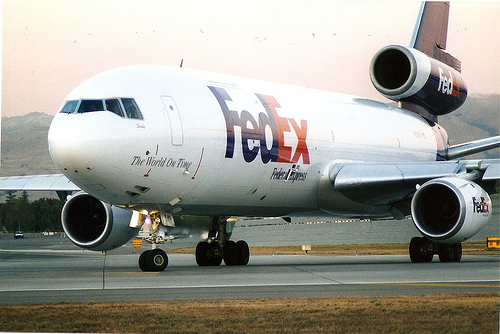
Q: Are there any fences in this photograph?
A: No, there are no fences.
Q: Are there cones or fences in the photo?
A: No, there are no fences or cones.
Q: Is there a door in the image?
A: Yes, there is a door.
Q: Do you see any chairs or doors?
A: Yes, there is a door.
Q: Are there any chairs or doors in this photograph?
A: Yes, there is a door.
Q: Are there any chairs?
A: No, there are no chairs.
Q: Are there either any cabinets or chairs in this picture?
A: No, there are no chairs or cabinets.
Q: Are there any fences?
A: No, there are no fences.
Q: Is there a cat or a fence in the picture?
A: No, there are no fences or cats.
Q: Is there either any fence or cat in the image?
A: No, there are no fences or cats.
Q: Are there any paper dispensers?
A: No, there are no paper dispensers.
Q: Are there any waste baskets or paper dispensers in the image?
A: No, there are no paper dispensers or waste baskets.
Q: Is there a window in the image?
A: Yes, there is a window.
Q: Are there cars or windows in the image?
A: Yes, there is a window.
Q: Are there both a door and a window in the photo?
A: Yes, there are both a window and a door.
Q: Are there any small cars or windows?
A: Yes, there is a small window.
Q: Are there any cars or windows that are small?
A: Yes, the window is small.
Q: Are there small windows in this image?
A: Yes, there is a small window.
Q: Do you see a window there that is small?
A: Yes, there is a small window.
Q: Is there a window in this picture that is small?
A: Yes, there is a window that is small.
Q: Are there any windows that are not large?
A: Yes, there is a small window.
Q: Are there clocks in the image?
A: No, there are no clocks.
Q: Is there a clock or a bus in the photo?
A: No, there are no clocks or buses.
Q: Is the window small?
A: Yes, the window is small.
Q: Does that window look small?
A: Yes, the window is small.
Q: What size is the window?
A: The window is small.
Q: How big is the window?
A: The window is small.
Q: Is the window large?
A: No, the window is small.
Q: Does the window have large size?
A: No, the window is small.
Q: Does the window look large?
A: No, the window is small.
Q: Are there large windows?
A: No, there is a window but it is small.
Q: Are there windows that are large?
A: No, there is a window but it is small.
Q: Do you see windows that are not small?
A: No, there is a window but it is small.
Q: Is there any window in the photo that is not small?
A: No, there is a window but it is small.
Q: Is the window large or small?
A: The window is small.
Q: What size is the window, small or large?
A: The window is small.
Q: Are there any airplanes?
A: Yes, there is an airplane.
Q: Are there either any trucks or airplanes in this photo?
A: Yes, there is an airplane.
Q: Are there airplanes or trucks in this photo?
A: Yes, there is an airplane.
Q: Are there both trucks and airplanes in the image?
A: No, there is an airplane but no trucks.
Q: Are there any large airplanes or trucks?
A: Yes, there is a large airplane.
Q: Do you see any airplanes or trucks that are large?
A: Yes, the airplane is large.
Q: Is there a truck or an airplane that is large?
A: Yes, the airplane is large.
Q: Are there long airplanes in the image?
A: Yes, there is a long airplane.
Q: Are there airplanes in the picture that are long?
A: Yes, there is an airplane that is long.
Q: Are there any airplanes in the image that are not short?
A: Yes, there is a long airplane.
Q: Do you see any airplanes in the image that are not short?
A: Yes, there is a long airplane.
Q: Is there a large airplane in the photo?
A: Yes, there is a large airplane.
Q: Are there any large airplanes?
A: Yes, there is a large airplane.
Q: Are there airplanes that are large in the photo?
A: Yes, there is a large airplane.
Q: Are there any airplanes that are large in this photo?
A: Yes, there is a large airplane.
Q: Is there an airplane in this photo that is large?
A: Yes, there is an airplane that is large.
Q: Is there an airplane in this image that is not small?
A: Yes, there is a large airplane.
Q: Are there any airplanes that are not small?
A: Yes, there is a large airplane.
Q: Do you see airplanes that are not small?
A: Yes, there is a large airplane.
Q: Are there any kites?
A: No, there are no kites.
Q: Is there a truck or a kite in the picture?
A: No, there are no kites or trucks.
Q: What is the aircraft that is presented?
A: The aircraft is an airplane.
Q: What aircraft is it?
A: The aircraft is an airplane.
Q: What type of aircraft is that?
A: This is an airplane.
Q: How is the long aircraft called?
A: The aircraft is an airplane.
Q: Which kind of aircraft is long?
A: The aircraft is an airplane.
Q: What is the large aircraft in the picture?
A: The aircraft is an airplane.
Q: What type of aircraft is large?
A: The aircraft is an airplane.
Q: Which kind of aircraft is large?
A: The aircraft is an airplane.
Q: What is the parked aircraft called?
A: The aircraft is an airplane.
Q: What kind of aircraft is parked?
A: The aircraft is an airplane.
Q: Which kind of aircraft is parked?
A: The aircraft is an airplane.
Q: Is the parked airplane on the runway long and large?
A: Yes, the airplane is long and large.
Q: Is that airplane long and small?
A: No, the airplane is long but large.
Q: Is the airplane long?
A: Yes, the airplane is long.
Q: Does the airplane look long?
A: Yes, the airplane is long.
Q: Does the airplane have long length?
A: Yes, the airplane is long.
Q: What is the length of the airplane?
A: The airplane is long.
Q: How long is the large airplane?
A: The airplane is long.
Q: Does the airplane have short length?
A: No, the airplane is long.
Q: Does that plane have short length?
A: No, the plane is long.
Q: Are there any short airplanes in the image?
A: No, there is an airplane but it is long.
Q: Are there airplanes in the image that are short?
A: No, there is an airplane but it is long.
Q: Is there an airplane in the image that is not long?
A: No, there is an airplane but it is long.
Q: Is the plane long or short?
A: The plane is long.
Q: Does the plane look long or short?
A: The plane is long.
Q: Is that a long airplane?
A: Yes, that is a long airplane.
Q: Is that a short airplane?
A: No, that is a long airplane.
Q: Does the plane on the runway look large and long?
A: Yes, the plane is large and long.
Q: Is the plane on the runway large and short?
A: No, the plane is large but long.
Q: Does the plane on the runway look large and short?
A: No, the plane is large but long.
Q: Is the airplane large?
A: Yes, the airplane is large.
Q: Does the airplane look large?
A: Yes, the airplane is large.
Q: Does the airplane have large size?
A: Yes, the airplane is large.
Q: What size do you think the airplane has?
A: The airplane has large size.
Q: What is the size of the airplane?
A: The airplane is large.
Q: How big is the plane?
A: The plane is large.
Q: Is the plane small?
A: No, the plane is large.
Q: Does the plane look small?
A: No, the plane is large.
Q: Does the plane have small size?
A: No, the plane is large.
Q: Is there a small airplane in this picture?
A: No, there is an airplane but it is large.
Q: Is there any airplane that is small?
A: No, there is an airplane but it is large.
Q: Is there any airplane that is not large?
A: No, there is an airplane but it is large.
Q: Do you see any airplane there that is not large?
A: No, there is an airplane but it is large.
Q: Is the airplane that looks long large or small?
A: The plane is large.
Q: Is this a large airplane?
A: Yes, this is a large airplane.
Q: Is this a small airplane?
A: No, this is a large airplane.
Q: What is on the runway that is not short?
A: The airplane is on the runway.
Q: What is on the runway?
A: The airplane is on the runway.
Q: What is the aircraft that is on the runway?
A: The aircraft is an airplane.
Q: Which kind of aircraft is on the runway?
A: The aircraft is an airplane.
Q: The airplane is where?
A: The airplane is on the runway.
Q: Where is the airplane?
A: The airplane is on the runway.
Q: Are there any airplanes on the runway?
A: Yes, there is an airplane on the runway.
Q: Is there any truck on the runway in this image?
A: No, there is an airplane on the runway.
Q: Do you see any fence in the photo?
A: No, there are no fences.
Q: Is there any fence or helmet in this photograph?
A: No, there are no fences or helmets.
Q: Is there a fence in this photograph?
A: No, there are no fences.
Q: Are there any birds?
A: No, there are no birds.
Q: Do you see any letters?
A: Yes, there are letters.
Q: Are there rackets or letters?
A: Yes, there are letters.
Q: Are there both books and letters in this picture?
A: No, there are letters but no books.